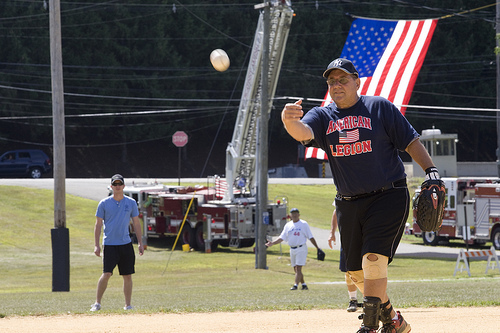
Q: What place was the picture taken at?
A: It was taken at the field.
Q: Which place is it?
A: It is a field.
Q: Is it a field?
A: Yes, it is a field.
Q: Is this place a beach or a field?
A: It is a field.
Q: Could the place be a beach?
A: No, it is a field.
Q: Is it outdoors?
A: Yes, it is outdoors.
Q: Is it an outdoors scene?
A: Yes, it is outdoors.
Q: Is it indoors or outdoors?
A: It is outdoors.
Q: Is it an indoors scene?
A: No, it is outdoors.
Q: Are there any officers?
A: No, there are no officers.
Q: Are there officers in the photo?
A: No, there are no officers.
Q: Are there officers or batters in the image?
A: No, there are no officers or batters.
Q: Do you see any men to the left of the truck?
A: Yes, there is a man to the left of the truck.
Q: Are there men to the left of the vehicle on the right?
A: Yes, there is a man to the left of the truck.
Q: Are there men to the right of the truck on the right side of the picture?
A: No, the man is to the left of the truck.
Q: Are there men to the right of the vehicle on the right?
A: No, the man is to the left of the truck.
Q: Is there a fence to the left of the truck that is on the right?
A: No, there is a man to the left of the truck.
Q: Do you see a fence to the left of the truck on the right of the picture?
A: No, there is a man to the left of the truck.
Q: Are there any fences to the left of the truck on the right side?
A: No, there is a man to the left of the truck.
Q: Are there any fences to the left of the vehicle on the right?
A: No, there is a man to the left of the truck.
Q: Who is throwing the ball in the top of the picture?
A: The man is throwing the ball.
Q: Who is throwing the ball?
A: The man is throwing the ball.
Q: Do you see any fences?
A: No, there are no fences.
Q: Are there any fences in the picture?
A: No, there are no fences.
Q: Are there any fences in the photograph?
A: No, there are no fences.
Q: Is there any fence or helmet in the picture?
A: No, there are no fences or helmets.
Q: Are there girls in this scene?
A: No, there are no girls.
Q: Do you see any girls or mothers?
A: No, there are no girls or mothers.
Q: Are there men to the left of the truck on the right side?
A: Yes, there is a man to the left of the truck.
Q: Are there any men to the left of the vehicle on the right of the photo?
A: Yes, there is a man to the left of the truck.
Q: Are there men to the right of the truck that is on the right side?
A: No, the man is to the left of the truck.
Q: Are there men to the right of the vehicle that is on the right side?
A: No, the man is to the left of the truck.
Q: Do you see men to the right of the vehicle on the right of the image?
A: No, the man is to the left of the truck.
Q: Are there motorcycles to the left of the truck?
A: No, there is a man to the left of the truck.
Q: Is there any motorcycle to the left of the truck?
A: No, there is a man to the left of the truck.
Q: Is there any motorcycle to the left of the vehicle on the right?
A: No, there is a man to the left of the truck.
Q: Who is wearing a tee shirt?
A: The man is wearing a tee shirt.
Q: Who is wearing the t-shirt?
A: The man is wearing a tee shirt.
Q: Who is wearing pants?
A: The man is wearing pants.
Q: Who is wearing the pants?
A: The man is wearing pants.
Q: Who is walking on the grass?
A: The man is walking on the grass.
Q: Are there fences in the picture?
A: No, there are no fences.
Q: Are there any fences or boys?
A: No, there are no fences or boys.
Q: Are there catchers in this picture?
A: No, there are no catchers.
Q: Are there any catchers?
A: No, there are no catchers.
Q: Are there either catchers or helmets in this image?
A: No, there are no catchers or helmets.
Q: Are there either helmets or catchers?
A: No, there are no catchers or helmets.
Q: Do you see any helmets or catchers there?
A: No, there are no catchers or helmets.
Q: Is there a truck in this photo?
A: Yes, there is a truck.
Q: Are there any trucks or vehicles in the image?
A: Yes, there is a truck.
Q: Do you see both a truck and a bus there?
A: No, there is a truck but no buses.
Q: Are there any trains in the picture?
A: No, there are no trains.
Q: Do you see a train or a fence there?
A: No, there are no trains or fences.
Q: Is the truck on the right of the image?
A: Yes, the truck is on the right of the image.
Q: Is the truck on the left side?
A: No, the truck is on the right of the image.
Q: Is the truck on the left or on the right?
A: The truck is on the right of the image.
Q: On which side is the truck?
A: The truck is on the right of the image.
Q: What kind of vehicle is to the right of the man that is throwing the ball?
A: The vehicle is a truck.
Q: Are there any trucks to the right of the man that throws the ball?
A: Yes, there is a truck to the right of the man.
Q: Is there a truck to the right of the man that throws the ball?
A: Yes, there is a truck to the right of the man.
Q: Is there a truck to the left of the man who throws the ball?
A: No, the truck is to the right of the man.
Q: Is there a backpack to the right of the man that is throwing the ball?
A: No, there is a truck to the right of the man.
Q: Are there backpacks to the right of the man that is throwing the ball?
A: No, there is a truck to the right of the man.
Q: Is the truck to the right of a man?
A: Yes, the truck is to the right of a man.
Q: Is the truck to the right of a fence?
A: No, the truck is to the right of a man.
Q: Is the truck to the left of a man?
A: No, the truck is to the right of a man.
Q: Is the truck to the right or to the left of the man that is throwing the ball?
A: The truck is to the right of the man.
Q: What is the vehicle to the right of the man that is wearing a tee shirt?
A: The vehicle is a truck.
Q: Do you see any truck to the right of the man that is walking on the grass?
A: Yes, there is a truck to the right of the man.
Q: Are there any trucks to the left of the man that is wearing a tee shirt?
A: No, the truck is to the right of the man.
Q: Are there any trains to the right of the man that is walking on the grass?
A: No, there is a truck to the right of the man.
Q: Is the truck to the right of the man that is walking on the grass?
A: Yes, the truck is to the right of the man.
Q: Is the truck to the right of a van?
A: No, the truck is to the right of the man.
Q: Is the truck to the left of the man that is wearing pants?
A: No, the truck is to the right of the man.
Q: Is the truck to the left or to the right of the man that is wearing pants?
A: The truck is to the right of the man.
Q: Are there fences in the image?
A: No, there are no fences.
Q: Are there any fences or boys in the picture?
A: No, there are no fences or boys.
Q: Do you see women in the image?
A: No, there are no women.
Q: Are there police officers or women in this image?
A: No, there are no women or police officers.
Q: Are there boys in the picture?
A: No, there are no boys.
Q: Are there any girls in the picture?
A: No, there are no girls.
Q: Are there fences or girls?
A: No, there are no girls or fences.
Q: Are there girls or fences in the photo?
A: No, there are no girls or fences.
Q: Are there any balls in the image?
A: Yes, there is a ball.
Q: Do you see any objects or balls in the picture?
A: Yes, there is a ball.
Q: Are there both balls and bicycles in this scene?
A: No, there is a ball but no bicycles.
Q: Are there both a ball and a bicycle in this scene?
A: No, there is a ball but no bicycles.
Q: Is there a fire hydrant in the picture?
A: No, there are no fire hydrants.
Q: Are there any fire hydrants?
A: No, there are no fire hydrants.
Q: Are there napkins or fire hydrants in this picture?
A: No, there are no fire hydrants or napkins.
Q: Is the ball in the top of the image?
A: Yes, the ball is in the top of the image.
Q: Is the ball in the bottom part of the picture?
A: No, the ball is in the top of the image.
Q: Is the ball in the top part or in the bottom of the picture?
A: The ball is in the top of the image.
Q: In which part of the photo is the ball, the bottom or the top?
A: The ball is in the top of the image.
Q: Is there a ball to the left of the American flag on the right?
A: Yes, there is a ball to the left of the American flag.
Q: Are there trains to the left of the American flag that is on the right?
A: No, there is a ball to the left of the American flag.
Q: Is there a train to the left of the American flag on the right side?
A: No, there is a ball to the left of the American flag.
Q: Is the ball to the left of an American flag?
A: Yes, the ball is to the left of an American flag.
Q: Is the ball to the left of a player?
A: No, the ball is to the left of an American flag.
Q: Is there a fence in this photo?
A: No, there are no fences.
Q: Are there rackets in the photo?
A: No, there are no rackets.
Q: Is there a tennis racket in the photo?
A: No, there are no rackets.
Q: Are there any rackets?
A: No, there are no rackets.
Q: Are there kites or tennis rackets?
A: No, there are no tennis rackets or kites.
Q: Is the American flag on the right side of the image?
A: Yes, the American flag is on the right of the image.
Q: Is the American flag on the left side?
A: No, the American flag is on the right of the image.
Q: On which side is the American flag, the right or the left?
A: The American flag is on the right of the image.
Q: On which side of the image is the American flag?
A: The American flag is on the right of the image.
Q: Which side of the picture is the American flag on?
A: The American flag is on the right of the image.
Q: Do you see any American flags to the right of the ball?
A: Yes, there is an American flag to the right of the ball.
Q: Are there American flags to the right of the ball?
A: Yes, there is an American flag to the right of the ball.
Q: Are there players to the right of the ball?
A: No, there is an American flag to the right of the ball.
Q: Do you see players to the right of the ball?
A: No, there is an American flag to the right of the ball.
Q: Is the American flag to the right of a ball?
A: Yes, the American flag is to the right of a ball.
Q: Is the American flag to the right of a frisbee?
A: No, the American flag is to the right of a ball.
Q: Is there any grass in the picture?
A: Yes, there is grass.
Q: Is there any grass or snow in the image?
A: Yes, there is grass.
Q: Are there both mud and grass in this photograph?
A: No, there is grass but no mud.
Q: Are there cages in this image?
A: No, there are no cages.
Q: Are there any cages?
A: No, there are no cages.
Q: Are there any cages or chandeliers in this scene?
A: No, there are no cages or chandeliers.